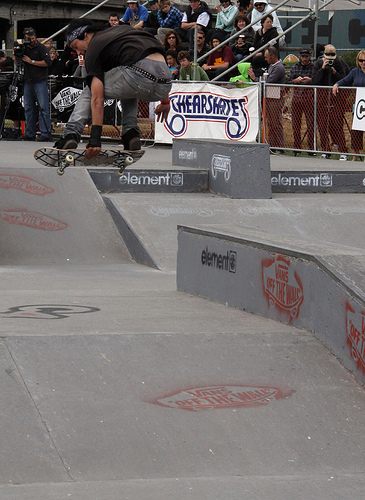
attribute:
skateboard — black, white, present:
[35, 147, 148, 177]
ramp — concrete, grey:
[6, 333, 365, 481]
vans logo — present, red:
[152, 379, 289, 409]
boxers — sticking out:
[134, 58, 173, 83]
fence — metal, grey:
[175, 77, 365, 162]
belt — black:
[127, 63, 176, 84]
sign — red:
[154, 84, 262, 144]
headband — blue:
[63, 25, 86, 44]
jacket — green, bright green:
[229, 59, 254, 86]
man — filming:
[11, 24, 52, 142]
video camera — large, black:
[13, 37, 35, 58]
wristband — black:
[86, 123, 106, 148]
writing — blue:
[171, 92, 250, 130]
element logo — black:
[197, 245, 242, 273]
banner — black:
[51, 77, 86, 122]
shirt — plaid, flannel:
[288, 61, 317, 99]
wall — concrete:
[168, 134, 274, 201]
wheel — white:
[123, 156, 133, 167]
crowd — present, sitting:
[51, 1, 365, 82]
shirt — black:
[81, 26, 165, 80]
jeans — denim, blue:
[62, 70, 180, 134]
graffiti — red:
[140, 380, 297, 411]